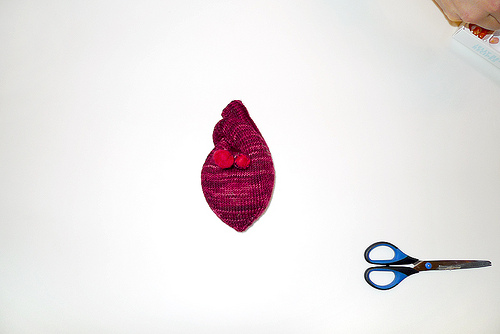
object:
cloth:
[198, 99, 276, 235]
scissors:
[364, 241, 496, 292]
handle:
[361, 241, 409, 291]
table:
[2, 1, 499, 331]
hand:
[434, 0, 499, 32]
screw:
[424, 262, 433, 270]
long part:
[430, 258, 495, 270]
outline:
[364, 241, 411, 292]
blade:
[433, 257, 494, 271]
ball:
[211, 148, 236, 169]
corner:
[432, 1, 500, 69]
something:
[450, 22, 500, 75]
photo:
[0, 0, 500, 333]